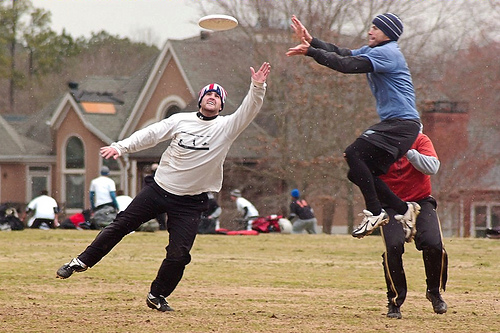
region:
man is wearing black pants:
[153, 254, 193, 298]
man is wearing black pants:
[159, 265, 184, 294]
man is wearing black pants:
[162, 255, 185, 279]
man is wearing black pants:
[164, 243, 224, 293]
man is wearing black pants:
[172, 241, 189, 268]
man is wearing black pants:
[174, 250, 186, 273]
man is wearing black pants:
[172, 235, 185, 257]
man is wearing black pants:
[159, 254, 171, 265]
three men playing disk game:
[82, 4, 463, 321]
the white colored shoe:
[346, 205, 397, 235]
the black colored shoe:
[55, 246, 102, 281]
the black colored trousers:
[75, 166, 208, 314]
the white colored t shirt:
[112, 98, 259, 208]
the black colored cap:
[372, 10, 409, 44]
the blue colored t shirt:
[347, 34, 429, 124]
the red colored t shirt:
[399, 166, 432, 205]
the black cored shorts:
[362, 106, 425, 170]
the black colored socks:
[338, 133, 405, 223]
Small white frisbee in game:
[191, 10, 243, 34]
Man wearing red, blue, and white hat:
[197, 83, 237, 110]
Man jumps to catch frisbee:
[283, 18, 420, 225]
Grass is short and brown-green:
[209, 251, 376, 328]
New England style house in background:
[41, 78, 209, 132]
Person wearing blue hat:
[285, 185, 303, 200]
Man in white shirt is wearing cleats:
[143, 291, 182, 319]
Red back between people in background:
[256, 217, 293, 232]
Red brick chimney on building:
[429, 99, 472, 159]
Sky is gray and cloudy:
[66, 12, 198, 38]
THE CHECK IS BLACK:
[373, 213, 378, 233]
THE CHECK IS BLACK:
[376, 213, 380, 230]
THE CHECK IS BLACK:
[369, 218, 381, 230]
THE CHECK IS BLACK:
[367, 217, 378, 234]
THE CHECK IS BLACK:
[372, 220, 382, 227]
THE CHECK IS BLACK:
[369, 213, 378, 217]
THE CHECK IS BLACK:
[371, 213, 382, 235]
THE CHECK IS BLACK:
[373, 220, 384, 234]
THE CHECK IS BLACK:
[367, 214, 380, 225]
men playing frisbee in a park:
[39, 2, 474, 314]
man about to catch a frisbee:
[182, 5, 434, 66]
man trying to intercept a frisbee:
[155, 46, 282, 162]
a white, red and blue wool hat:
[194, 77, 236, 109]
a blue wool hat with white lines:
[374, 9, 408, 41]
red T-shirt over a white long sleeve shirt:
[390, 132, 441, 198]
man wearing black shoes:
[53, 257, 173, 312]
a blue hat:
[286, 180, 306, 199]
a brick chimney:
[421, 86, 484, 161]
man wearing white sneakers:
[345, 194, 430, 239]